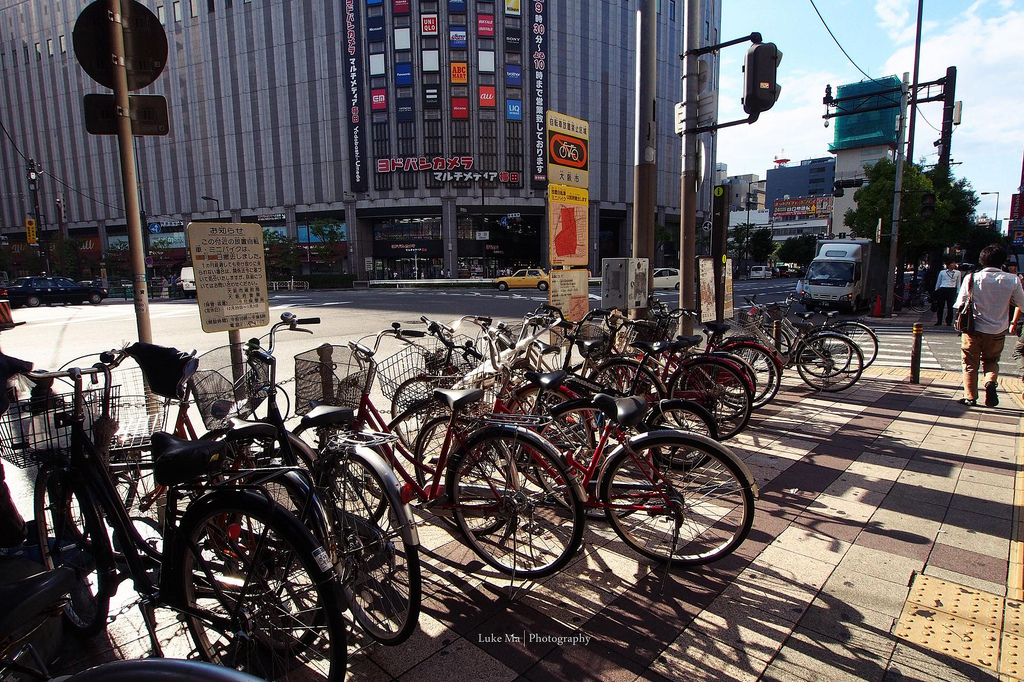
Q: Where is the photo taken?
A: At a bike rack.